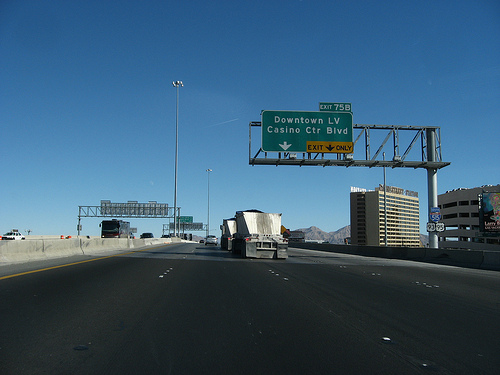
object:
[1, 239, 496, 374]
highway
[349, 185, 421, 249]
building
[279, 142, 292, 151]
arrow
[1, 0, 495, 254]
sky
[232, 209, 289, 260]
truck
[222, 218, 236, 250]
truck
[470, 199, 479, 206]
windows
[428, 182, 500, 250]
building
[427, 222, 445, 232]
signs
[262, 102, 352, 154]
sign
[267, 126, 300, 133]
text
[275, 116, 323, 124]
text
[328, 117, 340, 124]
text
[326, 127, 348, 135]
text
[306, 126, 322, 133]
text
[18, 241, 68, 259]
concrete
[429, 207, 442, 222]
sign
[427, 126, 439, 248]
pole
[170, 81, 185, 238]
light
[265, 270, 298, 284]
lines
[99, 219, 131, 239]
bus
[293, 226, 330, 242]
mountain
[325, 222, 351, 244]
mountain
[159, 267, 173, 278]
lines